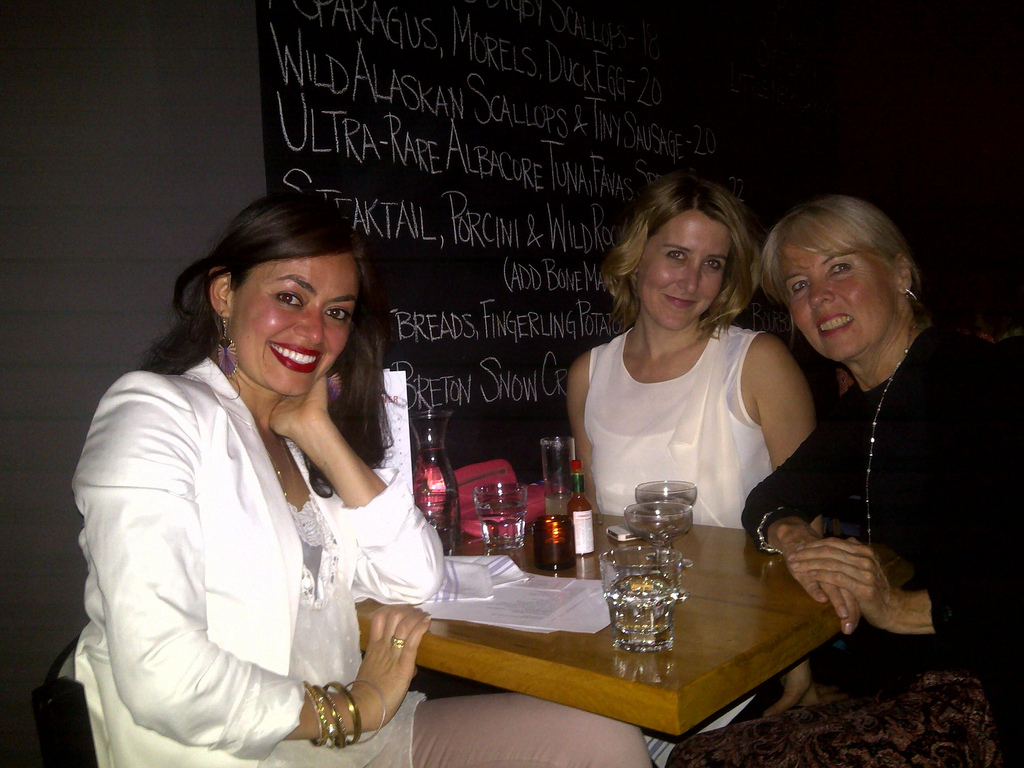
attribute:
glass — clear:
[579, 539, 685, 651]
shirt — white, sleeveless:
[573, 313, 777, 539]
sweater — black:
[737, 320, 1021, 742]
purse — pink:
[434, 448, 558, 559]